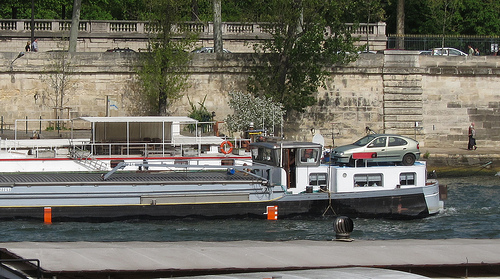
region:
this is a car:
[324, 118, 449, 172]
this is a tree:
[24, 39, 94, 156]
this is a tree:
[115, 11, 198, 125]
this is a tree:
[219, 68, 296, 158]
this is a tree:
[249, 0, 354, 144]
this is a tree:
[174, 78, 234, 153]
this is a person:
[459, 113, 494, 169]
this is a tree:
[40, 48, 80, 142]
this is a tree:
[246, 11, 286, 108]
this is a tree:
[424, 1, 484, 39]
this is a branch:
[121, 40, 143, 77]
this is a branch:
[121, 71, 167, 116]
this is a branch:
[224, 75, 250, 130]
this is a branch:
[256, 54, 315, 124]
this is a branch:
[296, 32, 322, 100]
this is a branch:
[307, 15, 362, 79]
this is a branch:
[232, 43, 271, 82]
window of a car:
[356, 130, 371, 148]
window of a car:
[374, 134, 391, 150]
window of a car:
[388, 135, 403, 147]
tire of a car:
[393, 147, 416, 166]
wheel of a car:
[351, 153, 369, 165]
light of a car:
[327, 145, 344, 155]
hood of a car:
[330, 137, 362, 153]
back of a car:
[398, 131, 435, 162]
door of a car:
[376, 138, 408, 171]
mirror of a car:
[365, 138, 375, 149]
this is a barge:
[18, 144, 460, 239]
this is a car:
[322, 121, 431, 173]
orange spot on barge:
[28, 200, 64, 230]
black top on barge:
[19, 160, 247, 195]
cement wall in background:
[14, 39, 499, 159]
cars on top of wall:
[16, 22, 497, 90]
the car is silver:
[320, 116, 421, 173]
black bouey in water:
[314, 202, 379, 244]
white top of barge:
[257, 127, 432, 197]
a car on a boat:
[331, 126, 416, 159]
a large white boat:
[1, 121, 446, 216]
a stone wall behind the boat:
[2, 71, 493, 131]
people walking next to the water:
[460, 121, 475, 146]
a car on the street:
[426, 41, 461, 56]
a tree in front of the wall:
[136, 5, 188, 107]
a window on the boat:
[300, 146, 315, 156]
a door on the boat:
[280, 146, 295, 183]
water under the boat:
[5, 218, 495, 240]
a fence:
[385, 37, 492, 53]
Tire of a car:
[401, 151, 416, 165]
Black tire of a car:
[402, 150, 419, 167]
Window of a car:
[388, 135, 404, 148]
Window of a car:
[385, 134, 408, 149]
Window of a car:
[386, 139, 408, 148]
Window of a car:
[374, 134, 386, 148]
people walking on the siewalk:
[462, 116, 479, 153]